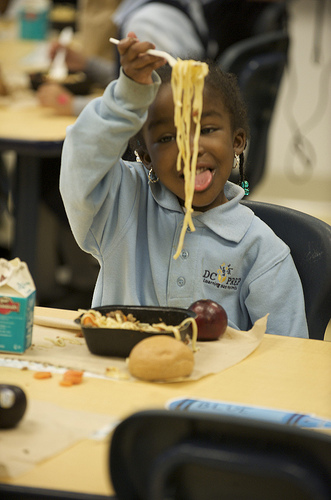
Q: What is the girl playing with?
A: Pasta.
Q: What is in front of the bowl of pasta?
A: Roll.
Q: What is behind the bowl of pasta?
A: Plum.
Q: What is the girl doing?
A: Eating.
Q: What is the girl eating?
A: Noodles.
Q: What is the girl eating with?
A: A spoon.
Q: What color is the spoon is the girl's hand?
A: White.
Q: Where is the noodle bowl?
A: On the table.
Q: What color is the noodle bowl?
A: Black.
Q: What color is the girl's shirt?
A: Gray.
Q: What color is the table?
A: Yellow.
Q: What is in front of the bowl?
A: A roll.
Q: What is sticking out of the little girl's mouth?
A: A tongue.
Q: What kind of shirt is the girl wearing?
A: A polo shirt.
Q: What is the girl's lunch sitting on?
A: A piece of paper.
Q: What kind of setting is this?
A: A school cafeteria.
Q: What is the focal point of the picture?
A: A girl eating lunch.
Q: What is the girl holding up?
A: A fork of spaghetti.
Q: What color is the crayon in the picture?
A: Blue.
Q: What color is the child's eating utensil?
A: White.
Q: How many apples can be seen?
A: One.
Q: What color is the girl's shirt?
A: Blue.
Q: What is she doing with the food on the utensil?
A: Holding it in the air.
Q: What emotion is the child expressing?
A: Happiness.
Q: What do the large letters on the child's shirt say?
A: DC PREP.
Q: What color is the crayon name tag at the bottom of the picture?
A: Blue.